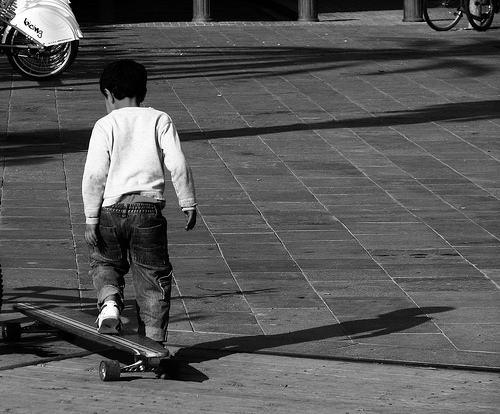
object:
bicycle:
[423, 0, 495, 33]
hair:
[100, 59, 147, 100]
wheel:
[99, 358, 121, 381]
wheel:
[0, 320, 22, 345]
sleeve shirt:
[156, 116, 197, 210]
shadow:
[158, 299, 455, 385]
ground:
[0, 88, 67, 206]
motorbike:
[0, 0, 82, 82]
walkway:
[1, 342, 496, 409]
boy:
[59, 66, 266, 374]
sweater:
[82, 107, 197, 224]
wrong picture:
[12, 15, 492, 381]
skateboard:
[12, 303, 168, 382]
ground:
[190, 235, 493, 365]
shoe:
[95, 300, 122, 334]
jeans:
[89, 195, 171, 340]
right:
[414, 13, 498, 411]